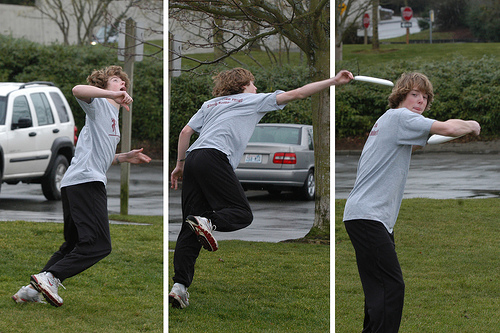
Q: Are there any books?
A: No, there are no books.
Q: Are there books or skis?
A: No, there are no books or skis.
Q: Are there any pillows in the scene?
A: No, there are no pillows.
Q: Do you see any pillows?
A: No, there are no pillows.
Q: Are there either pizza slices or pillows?
A: No, there are no pillows or pizza slices.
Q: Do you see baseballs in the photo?
A: No, there are no baseballs.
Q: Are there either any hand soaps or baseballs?
A: No, there are no baseballs or hand soaps.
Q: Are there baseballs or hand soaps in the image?
A: No, there are no baseballs or hand soaps.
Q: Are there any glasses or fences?
A: No, there are no fences or glasses.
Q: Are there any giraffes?
A: No, there are no giraffes.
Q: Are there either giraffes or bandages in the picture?
A: No, there are no giraffes or bandages.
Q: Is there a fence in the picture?
A: No, there are no fences.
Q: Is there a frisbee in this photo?
A: Yes, there is a frisbee.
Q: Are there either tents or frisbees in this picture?
A: Yes, there is a frisbee.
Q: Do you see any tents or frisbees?
A: Yes, there is a frisbee.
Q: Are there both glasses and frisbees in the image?
A: No, there is a frisbee but no glasses.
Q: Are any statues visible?
A: No, there are no statues.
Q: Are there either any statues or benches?
A: No, there are no statues or benches.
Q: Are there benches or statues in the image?
A: No, there are no statues or benches.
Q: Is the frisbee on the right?
A: Yes, the frisbee is on the right of the image.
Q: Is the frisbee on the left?
A: No, the frisbee is on the right of the image.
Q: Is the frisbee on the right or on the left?
A: The frisbee is on the right of the image.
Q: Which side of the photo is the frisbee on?
A: The frisbee is on the right of the image.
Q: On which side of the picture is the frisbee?
A: The frisbee is on the right of the image.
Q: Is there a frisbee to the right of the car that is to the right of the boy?
A: Yes, there is a frisbee to the right of the car.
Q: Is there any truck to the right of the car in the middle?
A: No, there is a frisbee to the right of the car.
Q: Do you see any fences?
A: No, there are no fences.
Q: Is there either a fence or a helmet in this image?
A: No, there are no fences or helmets.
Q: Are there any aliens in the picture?
A: No, there are no aliens.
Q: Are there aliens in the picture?
A: No, there are no aliens.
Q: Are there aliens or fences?
A: No, there are no aliens or fences.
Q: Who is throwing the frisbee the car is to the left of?
A: The boy is throwing the frisbee.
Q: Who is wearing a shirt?
A: The boy is wearing a shirt.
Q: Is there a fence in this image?
A: No, there are no fences.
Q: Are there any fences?
A: No, there are no fences.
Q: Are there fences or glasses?
A: No, there are no fences or glasses.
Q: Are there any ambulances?
A: No, there are no ambulances.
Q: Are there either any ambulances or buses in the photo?
A: No, there are no ambulances or buses.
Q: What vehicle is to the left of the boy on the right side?
A: The vehicle is a car.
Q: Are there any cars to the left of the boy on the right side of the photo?
A: Yes, there is a car to the left of the boy.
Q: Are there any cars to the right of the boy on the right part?
A: No, the car is to the left of the boy.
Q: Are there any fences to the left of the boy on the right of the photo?
A: No, there is a car to the left of the boy.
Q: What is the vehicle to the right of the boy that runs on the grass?
A: The vehicle is a car.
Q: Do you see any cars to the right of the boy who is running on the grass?
A: Yes, there is a car to the right of the boy.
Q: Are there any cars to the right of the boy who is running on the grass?
A: Yes, there is a car to the right of the boy.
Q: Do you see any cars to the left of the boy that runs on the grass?
A: No, the car is to the right of the boy.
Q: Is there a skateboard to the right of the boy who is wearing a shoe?
A: No, there is a car to the right of the boy.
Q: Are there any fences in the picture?
A: No, there are no fences.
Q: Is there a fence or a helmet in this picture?
A: No, there are no fences or helmets.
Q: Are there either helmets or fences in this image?
A: No, there are no fences or helmets.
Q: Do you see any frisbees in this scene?
A: Yes, there is a frisbee.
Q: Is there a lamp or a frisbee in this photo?
A: Yes, there is a frisbee.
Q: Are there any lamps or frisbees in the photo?
A: Yes, there is a frisbee.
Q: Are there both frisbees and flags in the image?
A: No, there is a frisbee but no flags.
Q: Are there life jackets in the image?
A: No, there are no life jackets.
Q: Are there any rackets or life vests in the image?
A: No, there are no life vests or rackets.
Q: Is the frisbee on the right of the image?
A: Yes, the frisbee is on the right of the image.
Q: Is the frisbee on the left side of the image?
A: No, the frisbee is on the right of the image.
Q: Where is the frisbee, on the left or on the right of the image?
A: The frisbee is on the right of the image.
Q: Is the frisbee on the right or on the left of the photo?
A: The frisbee is on the right of the image.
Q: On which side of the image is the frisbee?
A: The frisbee is on the right of the image.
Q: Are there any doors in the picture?
A: Yes, there is a door.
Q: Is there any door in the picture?
A: Yes, there is a door.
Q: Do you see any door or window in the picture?
A: Yes, there is a door.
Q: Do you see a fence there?
A: No, there are no fences.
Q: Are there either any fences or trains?
A: No, there are no fences or trains.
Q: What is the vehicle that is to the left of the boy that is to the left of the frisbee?
A: The vehicle is a car.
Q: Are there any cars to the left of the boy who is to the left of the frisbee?
A: Yes, there is a car to the left of the boy.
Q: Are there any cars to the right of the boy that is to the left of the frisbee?
A: No, the car is to the left of the boy.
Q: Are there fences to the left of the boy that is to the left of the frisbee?
A: No, there is a car to the left of the boy.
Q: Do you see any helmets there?
A: No, there are no helmets.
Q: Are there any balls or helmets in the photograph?
A: No, there are no helmets or balls.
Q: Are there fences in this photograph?
A: No, there are no fences.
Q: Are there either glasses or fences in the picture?
A: No, there are no fences or glasses.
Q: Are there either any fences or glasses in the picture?
A: No, there are no fences or glasses.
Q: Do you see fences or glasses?
A: No, there are no fences or glasses.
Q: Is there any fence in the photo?
A: No, there are no fences.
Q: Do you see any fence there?
A: No, there are no fences.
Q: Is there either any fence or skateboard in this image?
A: No, there are no fences or skateboards.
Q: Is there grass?
A: Yes, there is grass.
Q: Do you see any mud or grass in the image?
A: Yes, there is grass.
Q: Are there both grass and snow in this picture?
A: No, there is grass but no snow.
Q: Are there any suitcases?
A: No, there are no suitcases.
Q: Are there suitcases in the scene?
A: No, there are no suitcases.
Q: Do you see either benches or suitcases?
A: No, there are no suitcases or benches.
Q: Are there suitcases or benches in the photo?
A: No, there are no suitcases or benches.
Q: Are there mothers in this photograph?
A: No, there are no mothers.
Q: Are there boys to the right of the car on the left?
A: Yes, there is a boy to the right of the car.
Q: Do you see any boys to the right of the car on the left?
A: Yes, there is a boy to the right of the car.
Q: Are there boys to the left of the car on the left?
A: No, the boy is to the right of the car.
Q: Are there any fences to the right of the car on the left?
A: No, there is a boy to the right of the car.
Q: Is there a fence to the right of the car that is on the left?
A: No, there is a boy to the right of the car.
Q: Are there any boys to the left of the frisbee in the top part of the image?
A: Yes, there is a boy to the left of the frisbee.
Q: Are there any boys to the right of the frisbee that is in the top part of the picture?
A: No, the boy is to the left of the frisbee.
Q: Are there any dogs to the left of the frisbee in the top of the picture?
A: No, there is a boy to the left of the frisbee.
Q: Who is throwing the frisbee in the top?
A: The boy is throwing the frisbee.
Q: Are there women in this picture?
A: No, there are no women.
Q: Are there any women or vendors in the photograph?
A: No, there are no women or vendors.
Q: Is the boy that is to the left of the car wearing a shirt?
A: Yes, the boy is wearing a shirt.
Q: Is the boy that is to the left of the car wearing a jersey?
A: No, the boy is wearing a shirt.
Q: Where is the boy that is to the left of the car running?
A: The boy is running on the grass.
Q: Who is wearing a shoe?
A: The boy is wearing a shoe.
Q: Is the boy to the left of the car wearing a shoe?
A: Yes, the boy is wearing a shoe.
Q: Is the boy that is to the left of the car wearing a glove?
A: No, the boy is wearing a shoe.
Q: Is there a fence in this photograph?
A: No, there are no fences.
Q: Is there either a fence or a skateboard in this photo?
A: No, there are no fences or skateboards.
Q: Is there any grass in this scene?
A: Yes, there is grass.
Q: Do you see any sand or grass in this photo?
A: Yes, there is grass.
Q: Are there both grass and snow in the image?
A: No, there is grass but no snow.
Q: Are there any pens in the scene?
A: No, there are no pens.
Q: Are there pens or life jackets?
A: No, there are no pens or life jackets.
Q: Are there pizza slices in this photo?
A: No, there are no pizza slices.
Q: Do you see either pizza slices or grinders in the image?
A: No, there are no pizza slices or grinders.